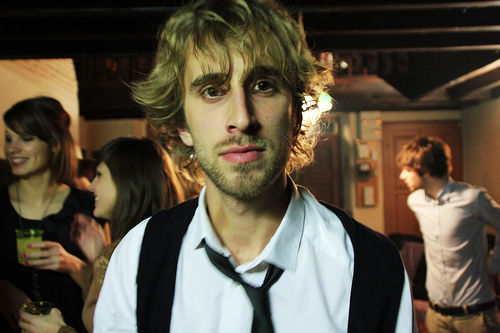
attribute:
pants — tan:
[396, 129, 498, 331]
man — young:
[426, 298, 498, 329]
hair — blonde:
[128, 3, 333, 180]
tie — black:
[200, 239, 287, 331]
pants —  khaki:
[418, 292, 498, 330]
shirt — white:
[89, 171, 419, 331]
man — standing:
[394, 130, 498, 331]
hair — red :
[387, 131, 457, 183]